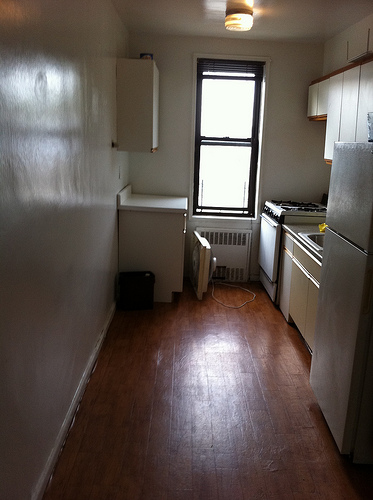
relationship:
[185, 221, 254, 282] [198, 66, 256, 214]
radiator under window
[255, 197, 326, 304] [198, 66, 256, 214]
range near window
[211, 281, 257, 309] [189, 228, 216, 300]
wire from fan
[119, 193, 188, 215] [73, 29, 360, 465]
white counter in kitchen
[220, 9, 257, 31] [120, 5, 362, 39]
light in ceiling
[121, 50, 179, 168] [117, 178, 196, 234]
cabinet above counter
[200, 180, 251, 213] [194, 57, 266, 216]
guard on a window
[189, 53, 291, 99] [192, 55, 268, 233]
blind on a window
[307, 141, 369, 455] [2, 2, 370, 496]
white fridge in kitchen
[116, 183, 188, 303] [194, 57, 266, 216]
white counter near window